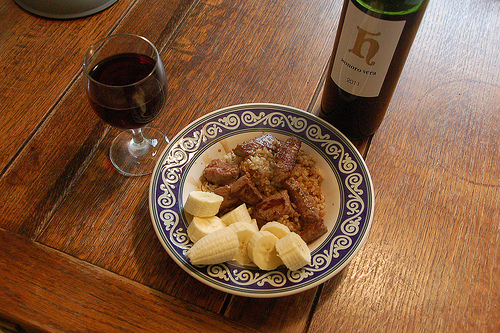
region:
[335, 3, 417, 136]
wine on the table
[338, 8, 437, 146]
bottle on the top of the table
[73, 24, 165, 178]
glass with wine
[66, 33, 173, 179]
glass on the top of the table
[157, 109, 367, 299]
bowl with food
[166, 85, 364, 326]
bowl with banana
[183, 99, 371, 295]
bowl with banana, rice and meat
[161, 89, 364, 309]
food on the plate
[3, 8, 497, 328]
wooden table with wine and food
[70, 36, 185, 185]
red wine on the glass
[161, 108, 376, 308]
blue and white rounded plate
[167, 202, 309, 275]
pieces of cut bananas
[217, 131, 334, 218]
rice and sausage mixed up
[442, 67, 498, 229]
table ring from a stain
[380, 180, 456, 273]
wooden table top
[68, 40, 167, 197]
glass wine glass on table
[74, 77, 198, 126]
dark purple win in glass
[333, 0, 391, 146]
green bottle of wine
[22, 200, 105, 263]
cuts in the wood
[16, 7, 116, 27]
silver pot on table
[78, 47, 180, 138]
the glass is half full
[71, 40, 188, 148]
the wine is red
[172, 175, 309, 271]
the bananas are white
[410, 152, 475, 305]
the table is brown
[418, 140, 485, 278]
the table is made of wood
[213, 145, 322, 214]
there is meat on the plate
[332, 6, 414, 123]
there is wine in the bottle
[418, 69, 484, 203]
there is circle marking on the table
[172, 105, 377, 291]
the plate has graffiti on the side of plate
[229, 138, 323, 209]
the rice is brown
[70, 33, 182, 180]
A glass of wine on the table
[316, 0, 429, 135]
A bottle of wine on the table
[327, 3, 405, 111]
A white label with a gold h and words on it on the bottle of wine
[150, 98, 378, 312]
A dish of food on a blue and white decorated plate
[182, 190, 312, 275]
Bananas cut into pieces on the plate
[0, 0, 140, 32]
A round end of a black object on the table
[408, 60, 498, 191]
An outline of a circle on the wooden table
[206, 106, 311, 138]
A white curvy design on the plate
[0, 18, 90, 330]
Part of a wooden table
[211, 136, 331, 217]
A meat dish on the plate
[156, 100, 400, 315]
the food is in the plate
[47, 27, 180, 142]
the wine is in the wine glass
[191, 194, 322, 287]
the banana is on the plate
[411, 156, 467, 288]
the table is made of wood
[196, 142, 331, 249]
the meat is brown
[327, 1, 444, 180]
the wine bottle is on the table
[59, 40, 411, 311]
the bottle is on the table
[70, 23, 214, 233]
the wine glass is on the table